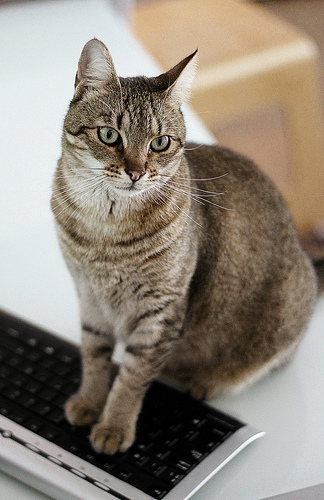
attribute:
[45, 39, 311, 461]
cat — dark brown, striped, grey, black, white, gray, brown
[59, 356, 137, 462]
paws — brown, light colored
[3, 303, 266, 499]
keyboard — grey, silver, black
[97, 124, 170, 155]
eyes — blue-green, grayish blue, green, olive colored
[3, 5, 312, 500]
desk — white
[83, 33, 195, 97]
ears — white, light brown, poined, pointed, brown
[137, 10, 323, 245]
floor — brown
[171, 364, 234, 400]
paws — light brown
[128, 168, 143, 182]
nose — pink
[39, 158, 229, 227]
whiskers — white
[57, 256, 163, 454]
legs — striped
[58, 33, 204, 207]
head — striped